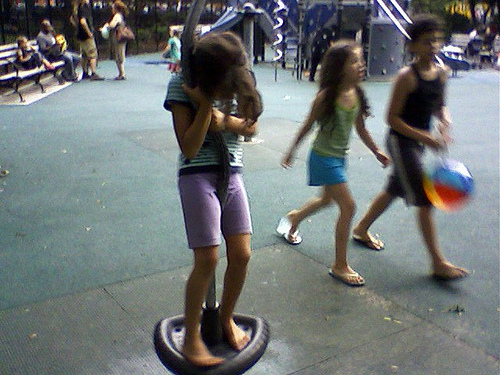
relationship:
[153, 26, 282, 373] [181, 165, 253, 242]
girl wearing shorts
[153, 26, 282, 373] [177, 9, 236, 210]
girl on pogo stick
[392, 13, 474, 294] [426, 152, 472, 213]
boy holding ball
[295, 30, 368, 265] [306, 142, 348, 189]
girl wearing shorts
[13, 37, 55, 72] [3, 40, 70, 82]
girl on bench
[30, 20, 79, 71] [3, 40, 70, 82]
person on bench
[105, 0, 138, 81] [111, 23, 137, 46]
woman has pocketbook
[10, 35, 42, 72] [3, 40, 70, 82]
girl on bench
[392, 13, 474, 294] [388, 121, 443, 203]
boy wearing shorts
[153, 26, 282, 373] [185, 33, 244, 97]
girl has head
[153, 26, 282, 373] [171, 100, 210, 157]
girl has arm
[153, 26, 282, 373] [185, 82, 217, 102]
girl has hand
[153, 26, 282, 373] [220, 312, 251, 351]
girl has foot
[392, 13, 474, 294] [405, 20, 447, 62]
boy has head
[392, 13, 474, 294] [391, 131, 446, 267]
boy has leg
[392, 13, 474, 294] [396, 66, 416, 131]
boy has arm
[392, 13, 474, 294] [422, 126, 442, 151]
boy has hand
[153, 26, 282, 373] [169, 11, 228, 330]
girl holding pole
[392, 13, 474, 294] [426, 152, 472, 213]
kid holding ball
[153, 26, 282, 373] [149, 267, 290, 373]
girl on swing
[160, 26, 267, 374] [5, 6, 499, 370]
girl at park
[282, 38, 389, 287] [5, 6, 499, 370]
girl at park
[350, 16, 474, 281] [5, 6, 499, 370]
boy at park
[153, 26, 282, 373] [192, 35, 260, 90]
girl has hair